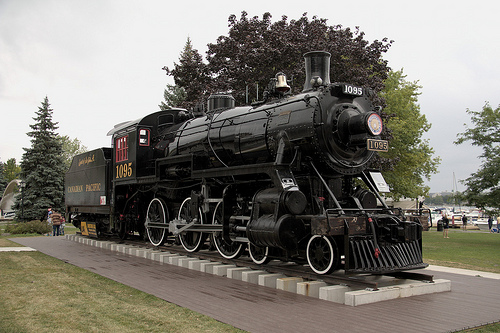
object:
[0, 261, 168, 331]
grass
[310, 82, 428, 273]
front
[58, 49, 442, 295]
on display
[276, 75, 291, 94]
bell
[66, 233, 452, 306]
display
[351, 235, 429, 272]
bumper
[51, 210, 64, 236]
people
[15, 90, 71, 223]
tree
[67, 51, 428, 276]
car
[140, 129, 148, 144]
window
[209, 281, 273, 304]
water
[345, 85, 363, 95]
number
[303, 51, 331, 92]
pipe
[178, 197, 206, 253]
wheel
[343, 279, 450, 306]
bricks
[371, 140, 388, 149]
numbers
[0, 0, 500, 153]
sky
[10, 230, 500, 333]
blocks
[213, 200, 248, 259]
wheel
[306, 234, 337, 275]
wheel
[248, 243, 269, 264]
wheel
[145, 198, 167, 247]
wheel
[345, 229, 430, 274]
grill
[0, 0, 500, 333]
park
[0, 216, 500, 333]
ground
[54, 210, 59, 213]
head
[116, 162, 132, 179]
number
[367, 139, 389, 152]
license plate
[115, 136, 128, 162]
window